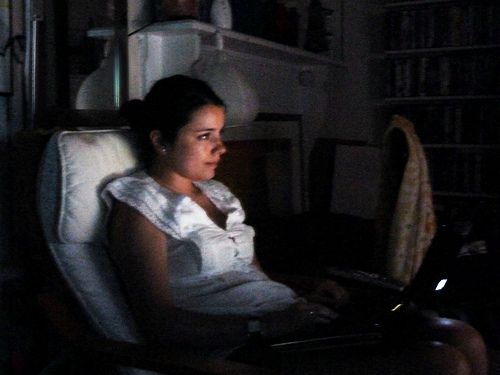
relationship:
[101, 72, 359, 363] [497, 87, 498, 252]
woman watching tv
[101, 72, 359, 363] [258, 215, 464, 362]
woman working on computer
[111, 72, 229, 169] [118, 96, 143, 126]
hair in ponytail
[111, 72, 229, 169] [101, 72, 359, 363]
hair of woman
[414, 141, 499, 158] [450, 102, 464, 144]
shelf contains book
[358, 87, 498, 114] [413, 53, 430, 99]
shelf contains book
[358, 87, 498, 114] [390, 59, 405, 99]
shelf contains book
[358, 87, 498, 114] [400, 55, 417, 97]
shelf contains book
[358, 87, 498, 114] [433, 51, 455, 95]
shelf contains book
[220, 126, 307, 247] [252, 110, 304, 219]
fireplace with frame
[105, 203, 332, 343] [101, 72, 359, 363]
arm of woman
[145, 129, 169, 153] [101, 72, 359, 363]
ear of woman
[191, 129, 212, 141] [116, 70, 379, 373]
eye of woman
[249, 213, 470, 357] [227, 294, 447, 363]
computer in lap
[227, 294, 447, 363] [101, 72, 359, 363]
lap of woman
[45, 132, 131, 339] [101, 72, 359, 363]
pillow behind woman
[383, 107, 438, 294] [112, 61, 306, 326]
blanket near woman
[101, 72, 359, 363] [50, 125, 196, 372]
woman sitting in chair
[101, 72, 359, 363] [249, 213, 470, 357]
woman playing on computer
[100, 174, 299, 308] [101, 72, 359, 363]
blouse on woman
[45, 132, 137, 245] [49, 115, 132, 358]
pillow from chair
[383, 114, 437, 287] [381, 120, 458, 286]
blanket hanging from chair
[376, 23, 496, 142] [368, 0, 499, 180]
books lined up on shelves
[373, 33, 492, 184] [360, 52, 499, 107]
shelves filled with books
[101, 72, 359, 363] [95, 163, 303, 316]
woman wearing shirt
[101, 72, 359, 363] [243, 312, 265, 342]
woman wearing black watch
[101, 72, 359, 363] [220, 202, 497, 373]
woman using laptop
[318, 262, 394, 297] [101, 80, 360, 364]
remote next to woman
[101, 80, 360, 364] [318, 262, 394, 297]
woman next to remote